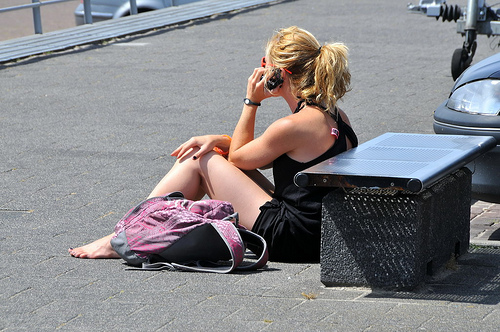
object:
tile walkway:
[0, 0, 499, 332]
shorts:
[245, 199, 320, 264]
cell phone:
[260, 68, 285, 91]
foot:
[68, 232, 122, 259]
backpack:
[109, 191, 267, 274]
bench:
[0, 0, 292, 65]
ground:
[0, 0, 499, 332]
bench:
[293, 132, 496, 293]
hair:
[263, 25, 352, 122]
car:
[433, 52, 500, 194]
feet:
[68, 232, 122, 259]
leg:
[68, 144, 276, 260]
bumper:
[433, 99, 499, 147]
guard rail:
[0, 0, 288, 65]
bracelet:
[243, 98, 261, 106]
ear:
[280, 68, 286, 86]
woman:
[68, 25, 359, 262]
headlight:
[444, 77, 499, 117]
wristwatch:
[243, 98, 261, 106]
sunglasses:
[261, 56, 292, 74]